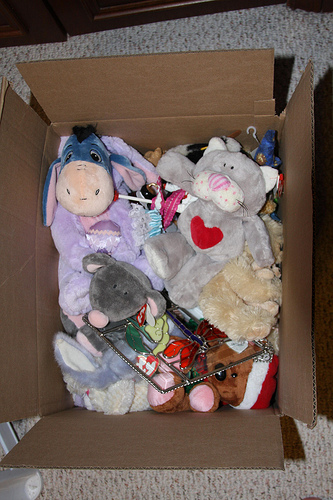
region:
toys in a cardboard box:
[5, 88, 298, 479]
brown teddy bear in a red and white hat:
[153, 333, 279, 414]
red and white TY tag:
[130, 352, 159, 377]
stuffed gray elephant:
[58, 243, 169, 356]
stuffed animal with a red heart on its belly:
[135, 126, 284, 302]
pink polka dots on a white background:
[186, 172, 243, 211]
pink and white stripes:
[207, 172, 230, 194]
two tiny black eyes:
[224, 160, 237, 172]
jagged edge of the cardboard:
[304, 349, 323, 426]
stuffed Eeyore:
[19, 117, 153, 224]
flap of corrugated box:
[0, 29, 321, 137]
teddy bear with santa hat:
[155, 322, 281, 419]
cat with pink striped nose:
[157, 135, 279, 213]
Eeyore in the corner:
[38, 123, 145, 228]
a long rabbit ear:
[44, 326, 118, 412]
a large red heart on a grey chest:
[178, 205, 246, 263]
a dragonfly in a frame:
[145, 303, 235, 369]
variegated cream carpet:
[35, 468, 331, 499]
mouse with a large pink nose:
[80, 251, 168, 339]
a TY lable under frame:
[122, 348, 164, 386]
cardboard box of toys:
[7, 55, 331, 474]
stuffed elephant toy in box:
[79, 249, 170, 333]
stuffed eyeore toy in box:
[38, 119, 150, 228]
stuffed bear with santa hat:
[146, 328, 286, 424]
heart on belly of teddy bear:
[189, 212, 226, 252]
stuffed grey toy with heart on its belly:
[140, 134, 280, 308]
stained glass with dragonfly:
[83, 288, 275, 398]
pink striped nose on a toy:
[206, 170, 231, 191]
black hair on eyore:
[66, 116, 96, 141]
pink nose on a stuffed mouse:
[86, 309, 109, 332]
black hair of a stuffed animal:
[63, 115, 110, 152]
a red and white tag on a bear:
[132, 348, 164, 381]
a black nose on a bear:
[208, 360, 236, 385]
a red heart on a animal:
[190, 206, 225, 258]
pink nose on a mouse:
[87, 300, 114, 335]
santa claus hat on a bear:
[253, 351, 278, 422]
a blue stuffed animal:
[249, 117, 289, 172]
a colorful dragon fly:
[162, 300, 245, 381]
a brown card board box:
[38, 412, 237, 490]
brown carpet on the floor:
[204, 466, 298, 498]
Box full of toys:
[36, 102, 284, 419]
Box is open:
[37, 415, 284, 480]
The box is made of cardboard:
[34, 416, 274, 473]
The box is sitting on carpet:
[53, 469, 288, 498]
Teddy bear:
[152, 333, 282, 408]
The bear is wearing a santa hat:
[143, 324, 290, 406]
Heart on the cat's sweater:
[176, 208, 246, 261]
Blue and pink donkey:
[41, 130, 131, 230]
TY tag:
[130, 348, 167, 383]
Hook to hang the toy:
[241, 119, 265, 147]